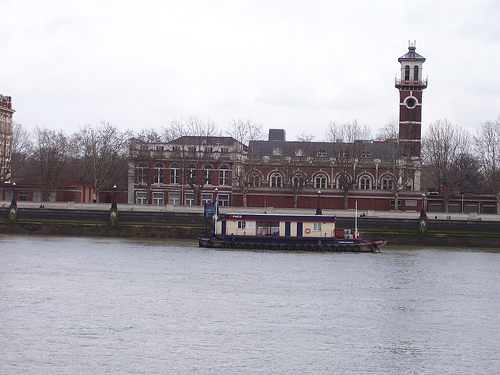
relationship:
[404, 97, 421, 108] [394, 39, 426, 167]
clock on clocktower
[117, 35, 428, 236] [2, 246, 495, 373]
building next to water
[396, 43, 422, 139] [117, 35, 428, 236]
clocktower attached to building